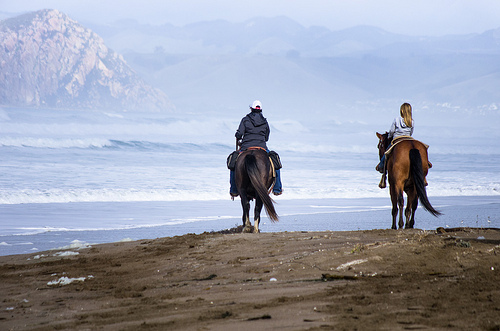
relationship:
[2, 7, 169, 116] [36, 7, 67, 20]
hill has tip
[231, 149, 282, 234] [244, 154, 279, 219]
horse has tail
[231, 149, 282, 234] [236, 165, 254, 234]
horse has back leg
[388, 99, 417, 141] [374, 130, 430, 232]
girl on horse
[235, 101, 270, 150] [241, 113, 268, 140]
man has back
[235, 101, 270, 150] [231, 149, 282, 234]
man riding horse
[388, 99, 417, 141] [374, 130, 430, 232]
girl riding horse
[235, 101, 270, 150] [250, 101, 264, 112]
man wearing cap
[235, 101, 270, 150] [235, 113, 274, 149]
man wearing winter jacket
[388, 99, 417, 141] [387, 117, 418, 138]
girl wearing hoody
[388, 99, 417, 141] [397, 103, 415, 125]
girl has hair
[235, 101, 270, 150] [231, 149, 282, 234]
man on horse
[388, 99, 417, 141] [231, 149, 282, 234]
girl on horse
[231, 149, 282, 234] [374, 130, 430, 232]
horse being ridden with horse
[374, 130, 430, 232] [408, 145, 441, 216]
horse has tail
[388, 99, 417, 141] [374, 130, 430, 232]
girl riding on horse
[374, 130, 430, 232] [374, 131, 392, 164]
horse has head